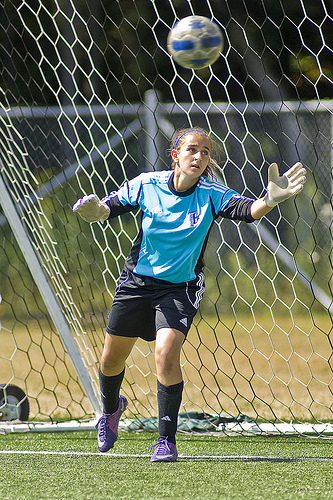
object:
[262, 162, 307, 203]
gloves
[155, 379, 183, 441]
sock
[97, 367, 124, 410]
sock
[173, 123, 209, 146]
headband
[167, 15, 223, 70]
ball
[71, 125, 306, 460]
woman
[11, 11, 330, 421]
net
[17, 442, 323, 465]
line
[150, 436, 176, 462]
shoe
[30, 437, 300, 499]
grass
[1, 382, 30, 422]
tire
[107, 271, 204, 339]
shorts